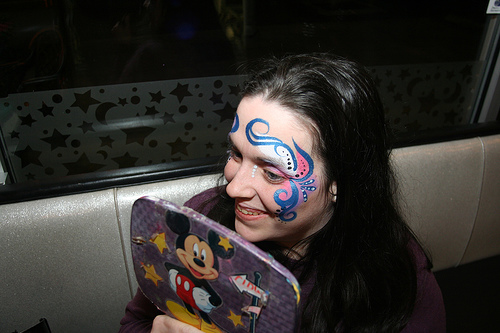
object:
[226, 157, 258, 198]
nose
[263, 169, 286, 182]
eye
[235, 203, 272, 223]
her mouth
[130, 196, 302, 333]
mirror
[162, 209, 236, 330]
mickey mouse art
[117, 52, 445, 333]
woman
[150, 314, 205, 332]
hand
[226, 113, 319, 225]
paint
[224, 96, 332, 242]
face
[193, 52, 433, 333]
hair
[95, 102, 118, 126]
moon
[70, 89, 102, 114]
star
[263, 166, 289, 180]
pink eye shadow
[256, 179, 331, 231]
cheek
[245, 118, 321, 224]
face paint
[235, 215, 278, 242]
chin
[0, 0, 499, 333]
picture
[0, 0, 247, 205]
night time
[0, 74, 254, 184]
banner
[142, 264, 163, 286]
yellow stars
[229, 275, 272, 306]
arrow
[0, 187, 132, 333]
seat cushion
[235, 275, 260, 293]
pink writing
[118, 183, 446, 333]
shirt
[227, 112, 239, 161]
face paint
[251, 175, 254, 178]
dots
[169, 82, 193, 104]
stars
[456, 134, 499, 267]
cushions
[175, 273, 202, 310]
mickey's shorts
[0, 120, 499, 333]
bench